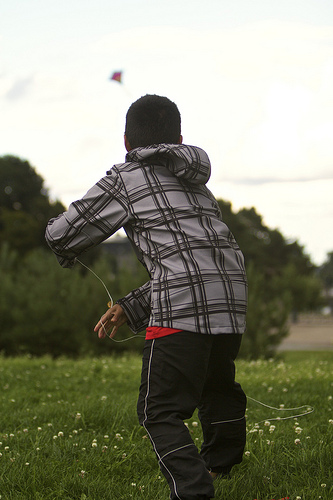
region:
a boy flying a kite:
[44, 93, 246, 498]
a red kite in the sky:
[110, 69, 123, 82]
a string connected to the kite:
[73, 254, 314, 430]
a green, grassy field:
[0, 350, 332, 499]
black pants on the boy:
[137, 324, 246, 498]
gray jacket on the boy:
[44, 143, 248, 334]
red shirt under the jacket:
[144, 326, 180, 341]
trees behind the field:
[0, 153, 331, 355]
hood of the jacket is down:
[125, 143, 210, 183]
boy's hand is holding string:
[92, 302, 127, 339]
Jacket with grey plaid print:
[43, 139, 267, 346]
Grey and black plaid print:
[165, 238, 227, 318]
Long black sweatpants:
[137, 311, 251, 498]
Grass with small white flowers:
[9, 366, 136, 493]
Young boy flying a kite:
[32, 58, 276, 369]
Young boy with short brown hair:
[33, 88, 293, 389]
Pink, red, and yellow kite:
[81, 50, 141, 99]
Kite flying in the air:
[31, 24, 224, 145]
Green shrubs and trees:
[0, 142, 331, 371]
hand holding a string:
[68, 258, 143, 361]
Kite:
[86, 48, 152, 89]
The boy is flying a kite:
[82, 59, 224, 339]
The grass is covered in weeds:
[16, 350, 140, 477]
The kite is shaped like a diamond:
[94, 49, 139, 91]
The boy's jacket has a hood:
[112, 135, 237, 203]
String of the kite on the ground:
[243, 374, 313, 466]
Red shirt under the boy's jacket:
[135, 310, 195, 346]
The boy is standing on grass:
[18, 350, 135, 476]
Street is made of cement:
[283, 311, 327, 345]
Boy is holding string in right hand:
[69, 283, 156, 353]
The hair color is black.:
[130, 100, 172, 139]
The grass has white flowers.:
[42, 409, 114, 457]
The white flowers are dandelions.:
[48, 418, 123, 459]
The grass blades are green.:
[48, 453, 111, 483]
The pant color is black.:
[152, 338, 249, 469]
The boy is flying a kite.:
[90, 62, 147, 87]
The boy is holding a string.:
[84, 265, 136, 350]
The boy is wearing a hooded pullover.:
[80, 160, 273, 317]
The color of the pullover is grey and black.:
[151, 178, 232, 307]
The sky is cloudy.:
[181, 37, 288, 96]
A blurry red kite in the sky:
[107, 58, 125, 93]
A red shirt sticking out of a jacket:
[136, 319, 187, 343]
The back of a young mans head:
[116, 88, 189, 147]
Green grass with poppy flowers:
[38, 410, 124, 472]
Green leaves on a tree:
[0, 160, 35, 239]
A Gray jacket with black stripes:
[161, 198, 217, 314]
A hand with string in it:
[89, 299, 124, 343]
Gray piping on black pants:
[136, 339, 159, 424]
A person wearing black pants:
[138, 338, 255, 498]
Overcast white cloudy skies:
[217, 99, 331, 171]